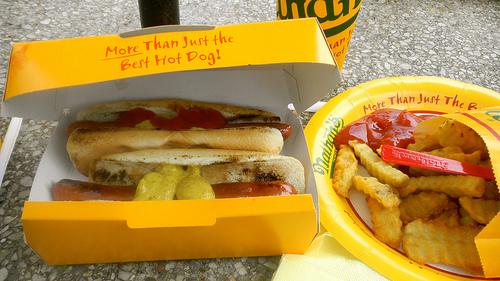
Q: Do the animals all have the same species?
A: Yes, all the animals are dogs.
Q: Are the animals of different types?
A: No, all the animals are dogs.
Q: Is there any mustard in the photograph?
A: Yes, there is mustard.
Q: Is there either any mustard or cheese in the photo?
A: Yes, there is mustard.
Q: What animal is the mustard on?
A: The mustard is on the dog.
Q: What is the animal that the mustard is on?
A: The animal is a dog.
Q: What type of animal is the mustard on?
A: The mustard is on the dog.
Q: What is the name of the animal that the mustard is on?
A: The animal is a dog.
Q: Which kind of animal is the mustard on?
A: The mustard is on the dog.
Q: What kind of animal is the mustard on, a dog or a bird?
A: The mustard is on a dog.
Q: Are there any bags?
A: Yes, there is a bag.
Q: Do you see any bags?
A: Yes, there is a bag.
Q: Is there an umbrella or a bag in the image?
A: Yes, there is a bag.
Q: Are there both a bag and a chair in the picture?
A: No, there is a bag but no chairs.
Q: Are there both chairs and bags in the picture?
A: No, there is a bag but no chairs.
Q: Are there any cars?
A: No, there are no cars.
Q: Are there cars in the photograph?
A: No, there are no cars.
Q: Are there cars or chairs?
A: No, there are no cars or chairs.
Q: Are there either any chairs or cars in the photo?
A: No, there are no cars or chairs.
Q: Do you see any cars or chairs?
A: No, there are no cars or chairs.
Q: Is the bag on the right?
A: Yes, the bag is on the right of the image.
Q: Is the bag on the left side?
A: No, the bag is on the right of the image.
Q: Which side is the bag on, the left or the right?
A: The bag is on the right of the image.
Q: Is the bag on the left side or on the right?
A: The bag is on the right of the image.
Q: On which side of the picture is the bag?
A: The bag is on the right of the image.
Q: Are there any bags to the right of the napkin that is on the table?
A: Yes, there is a bag to the right of the napkin.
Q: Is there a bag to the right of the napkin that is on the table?
A: Yes, there is a bag to the right of the napkin.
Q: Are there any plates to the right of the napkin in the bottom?
A: No, there is a bag to the right of the napkin.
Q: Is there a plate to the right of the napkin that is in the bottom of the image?
A: No, there is a bag to the right of the napkin.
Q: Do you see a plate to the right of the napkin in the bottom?
A: No, there is a bag to the right of the napkin.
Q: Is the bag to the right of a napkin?
A: Yes, the bag is to the right of a napkin.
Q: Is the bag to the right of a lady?
A: No, the bag is to the right of a napkin.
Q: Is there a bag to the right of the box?
A: Yes, there is a bag to the right of the box.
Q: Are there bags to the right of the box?
A: Yes, there is a bag to the right of the box.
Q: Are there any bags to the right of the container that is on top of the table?
A: Yes, there is a bag to the right of the box.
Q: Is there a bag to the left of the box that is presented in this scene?
A: No, the bag is to the right of the box.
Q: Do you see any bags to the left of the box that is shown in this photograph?
A: No, the bag is to the right of the box.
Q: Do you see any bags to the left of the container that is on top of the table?
A: No, the bag is to the right of the box.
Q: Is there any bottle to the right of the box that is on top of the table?
A: No, there is a bag to the right of the box.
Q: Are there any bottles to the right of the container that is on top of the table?
A: No, there is a bag to the right of the box.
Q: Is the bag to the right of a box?
A: Yes, the bag is to the right of a box.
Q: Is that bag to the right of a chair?
A: No, the bag is to the right of a box.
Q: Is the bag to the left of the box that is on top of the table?
A: No, the bag is to the right of the box.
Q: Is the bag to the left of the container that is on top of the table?
A: No, the bag is to the right of the box.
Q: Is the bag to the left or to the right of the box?
A: The bag is to the right of the box.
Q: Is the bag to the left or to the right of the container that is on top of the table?
A: The bag is to the right of the box.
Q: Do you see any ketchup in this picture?
A: Yes, there is ketchup.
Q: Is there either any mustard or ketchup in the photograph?
A: Yes, there is ketchup.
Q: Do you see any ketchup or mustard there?
A: Yes, there is ketchup.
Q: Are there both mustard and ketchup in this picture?
A: Yes, there are both ketchup and mustard.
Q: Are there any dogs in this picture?
A: Yes, there is a dog.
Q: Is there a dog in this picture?
A: Yes, there is a dog.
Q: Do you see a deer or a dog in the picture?
A: Yes, there is a dog.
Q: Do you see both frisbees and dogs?
A: No, there is a dog but no frisbees.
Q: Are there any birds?
A: No, there are no birds.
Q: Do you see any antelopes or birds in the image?
A: No, there are no birds or antelopes.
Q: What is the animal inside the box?
A: The animal is a dog.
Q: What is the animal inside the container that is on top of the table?
A: The animal is a dog.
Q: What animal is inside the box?
A: The animal is a dog.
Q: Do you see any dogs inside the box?
A: Yes, there is a dog inside the box.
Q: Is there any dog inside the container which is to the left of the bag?
A: Yes, there is a dog inside the box.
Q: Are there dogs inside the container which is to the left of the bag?
A: Yes, there is a dog inside the box.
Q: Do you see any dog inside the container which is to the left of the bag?
A: Yes, there is a dog inside the box.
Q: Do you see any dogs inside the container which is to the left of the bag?
A: Yes, there is a dog inside the box.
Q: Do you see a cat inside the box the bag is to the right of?
A: No, there is a dog inside the box.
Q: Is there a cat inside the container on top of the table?
A: No, there is a dog inside the box.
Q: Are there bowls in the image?
A: No, there are no bowls.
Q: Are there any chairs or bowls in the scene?
A: No, there are no bowls or chairs.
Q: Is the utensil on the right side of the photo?
A: Yes, the utensil is on the right of the image.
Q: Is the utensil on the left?
A: No, the utensil is on the right of the image.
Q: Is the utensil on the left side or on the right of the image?
A: The utensil is on the right of the image.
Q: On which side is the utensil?
A: The utensil is on the right of the image.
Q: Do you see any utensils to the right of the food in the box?
A: Yes, there is a utensil to the right of the food.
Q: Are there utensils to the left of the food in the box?
A: No, the utensil is to the right of the food.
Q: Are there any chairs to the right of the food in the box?
A: No, there is a utensil to the right of the food.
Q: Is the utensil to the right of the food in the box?
A: Yes, the utensil is to the right of the food.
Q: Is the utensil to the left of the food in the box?
A: No, the utensil is to the right of the food.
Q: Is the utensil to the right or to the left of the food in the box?
A: The utensil is to the right of the food.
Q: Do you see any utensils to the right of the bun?
A: Yes, there is a utensil to the right of the bun.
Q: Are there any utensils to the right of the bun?
A: Yes, there is a utensil to the right of the bun.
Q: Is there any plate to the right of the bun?
A: No, there is a utensil to the right of the bun.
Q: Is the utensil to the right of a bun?
A: Yes, the utensil is to the right of a bun.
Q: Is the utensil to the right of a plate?
A: No, the utensil is to the right of a bun.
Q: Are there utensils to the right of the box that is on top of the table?
A: Yes, there is a utensil to the right of the box.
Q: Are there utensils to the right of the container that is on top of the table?
A: Yes, there is a utensil to the right of the box.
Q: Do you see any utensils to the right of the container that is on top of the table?
A: Yes, there is a utensil to the right of the box.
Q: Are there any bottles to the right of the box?
A: No, there is a utensil to the right of the box.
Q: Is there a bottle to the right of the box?
A: No, there is a utensil to the right of the box.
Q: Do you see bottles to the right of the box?
A: No, there is a utensil to the right of the box.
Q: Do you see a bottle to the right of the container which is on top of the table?
A: No, there is a utensil to the right of the box.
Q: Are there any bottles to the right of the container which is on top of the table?
A: No, there is a utensil to the right of the box.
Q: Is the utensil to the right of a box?
A: Yes, the utensil is to the right of a box.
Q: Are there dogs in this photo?
A: Yes, there are dogs.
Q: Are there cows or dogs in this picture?
A: Yes, there are dogs.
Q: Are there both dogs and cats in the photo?
A: No, there are dogs but no cats.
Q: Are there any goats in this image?
A: No, there are no goats.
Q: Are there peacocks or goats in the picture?
A: No, there are no goats or peacocks.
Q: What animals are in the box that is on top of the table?
A: The animals are dogs.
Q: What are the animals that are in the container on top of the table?
A: The animals are dogs.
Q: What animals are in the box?
A: The animals are dogs.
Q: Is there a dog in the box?
A: Yes, there are dogs in the box.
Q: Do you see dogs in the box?
A: Yes, there are dogs in the box.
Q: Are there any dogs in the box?
A: Yes, there are dogs in the box.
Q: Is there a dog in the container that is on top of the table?
A: Yes, there are dogs in the box.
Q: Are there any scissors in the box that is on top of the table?
A: No, there are dogs in the box.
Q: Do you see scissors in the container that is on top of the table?
A: No, there are dogs in the box.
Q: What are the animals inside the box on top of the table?
A: The animals are dogs.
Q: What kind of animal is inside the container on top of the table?
A: The animals are dogs.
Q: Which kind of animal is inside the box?
A: The animals are dogs.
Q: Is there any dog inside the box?
A: Yes, there are dogs inside the box.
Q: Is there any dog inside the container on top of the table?
A: Yes, there are dogs inside the box.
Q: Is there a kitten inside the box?
A: No, there are dogs inside the box.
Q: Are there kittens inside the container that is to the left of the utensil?
A: No, there are dogs inside the box.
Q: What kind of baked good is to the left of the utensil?
A: The food is a bun.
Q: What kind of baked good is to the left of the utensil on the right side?
A: The food is a bun.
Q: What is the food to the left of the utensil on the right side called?
A: The food is a bun.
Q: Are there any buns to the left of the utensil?
A: Yes, there is a bun to the left of the utensil.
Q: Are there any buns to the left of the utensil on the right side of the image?
A: Yes, there is a bun to the left of the utensil.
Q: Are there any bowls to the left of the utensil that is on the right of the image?
A: No, there is a bun to the left of the utensil.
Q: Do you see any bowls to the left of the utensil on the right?
A: No, there is a bun to the left of the utensil.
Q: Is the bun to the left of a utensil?
A: Yes, the bun is to the left of a utensil.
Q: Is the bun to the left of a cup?
A: No, the bun is to the left of a utensil.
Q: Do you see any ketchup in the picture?
A: Yes, there is ketchup.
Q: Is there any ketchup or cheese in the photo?
A: Yes, there is ketchup.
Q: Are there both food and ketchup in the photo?
A: Yes, there are both ketchup and food.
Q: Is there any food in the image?
A: Yes, there is food.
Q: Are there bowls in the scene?
A: No, there are no bowls.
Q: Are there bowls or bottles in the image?
A: No, there are no bowls or bottles.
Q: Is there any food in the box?
A: Yes, there is food in the box.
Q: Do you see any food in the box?
A: Yes, there is food in the box.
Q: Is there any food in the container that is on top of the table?
A: Yes, there is food in the box.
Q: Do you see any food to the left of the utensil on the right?
A: Yes, there is food to the left of the utensil.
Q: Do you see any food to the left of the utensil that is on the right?
A: Yes, there is food to the left of the utensil.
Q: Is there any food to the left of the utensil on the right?
A: Yes, there is food to the left of the utensil.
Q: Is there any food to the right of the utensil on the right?
A: No, the food is to the left of the utensil.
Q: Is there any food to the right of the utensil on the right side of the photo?
A: No, the food is to the left of the utensil.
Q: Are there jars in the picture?
A: No, there are no jars.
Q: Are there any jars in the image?
A: No, there are no jars.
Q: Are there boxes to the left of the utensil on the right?
A: Yes, there is a box to the left of the utensil.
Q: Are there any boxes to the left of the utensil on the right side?
A: Yes, there is a box to the left of the utensil.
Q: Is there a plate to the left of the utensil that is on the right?
A: No, there is a box to the left of the utensil.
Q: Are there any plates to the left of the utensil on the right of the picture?
A: No, there is a box to the left of the utensil.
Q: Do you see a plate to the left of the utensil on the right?
A: No, there is a box to the left of the utensil.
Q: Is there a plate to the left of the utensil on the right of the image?
A: No, there is a box to the left of the utensil.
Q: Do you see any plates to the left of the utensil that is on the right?
A: No, there is a box to the left of the utensil.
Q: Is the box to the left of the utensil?
A: Yes, the box is to the left of the utensil.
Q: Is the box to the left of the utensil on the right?
A: Yes, the box is to the left of the utensil.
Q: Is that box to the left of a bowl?
A: No, the box is to the left of the utensil.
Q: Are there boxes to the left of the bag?
A: Yes, there is a box to the left of the bag.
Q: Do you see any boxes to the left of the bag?
A: Yes, there is a box to the left of the bag.